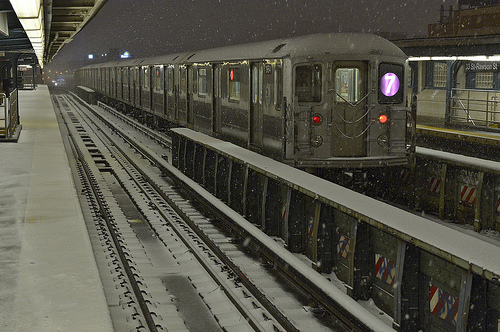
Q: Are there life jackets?
A: No, there are no life jackets.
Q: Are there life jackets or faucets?
A: No, there are no life jackets or faucets.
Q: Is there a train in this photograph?
A: Yes, there is a train.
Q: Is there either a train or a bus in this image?
A: Yes, there is a train.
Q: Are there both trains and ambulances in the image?
A: No, there is a train but no ambulances.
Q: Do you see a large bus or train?
A: Yes, there is a large train.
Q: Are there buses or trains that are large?
A: Yes, the train is large.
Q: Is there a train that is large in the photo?
A: Yes, there is a large train.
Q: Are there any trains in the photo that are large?
A: Yes, there is a train that is large.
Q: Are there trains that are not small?
A: Yes, there is a large train.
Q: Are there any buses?
A: No, there are no buses.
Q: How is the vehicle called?
A: The vehicle is a train.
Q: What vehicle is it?
A: The vehicle is a train.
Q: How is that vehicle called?
A: That is a train.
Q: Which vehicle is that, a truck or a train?
A: That is a train.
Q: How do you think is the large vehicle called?
A: The vehicle is a train.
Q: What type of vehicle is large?
A: The vehicle is a train.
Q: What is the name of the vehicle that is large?
A: The vehicle is a train.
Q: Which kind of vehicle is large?
A: The vehicle is a train.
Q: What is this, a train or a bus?
A: This is a train.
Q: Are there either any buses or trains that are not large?
A: No, there is a train but it is large.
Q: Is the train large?
A: Yes, the train is large.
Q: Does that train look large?
A: Yes, the train is large.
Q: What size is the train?
A: The train is large.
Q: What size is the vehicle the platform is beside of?
A: The train is large.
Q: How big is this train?
A: The train is large.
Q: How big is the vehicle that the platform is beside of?
A: The train is large.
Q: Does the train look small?
A: No, the train is large.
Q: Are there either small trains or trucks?
A: No, there is a train but it is large.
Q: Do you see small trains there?
A: No, there is a train but it is large.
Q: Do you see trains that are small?
A: No, there is a train but it is large.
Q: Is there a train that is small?
A: No, there is a train but it is large.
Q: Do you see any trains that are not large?
A: No, there is a train but it is large.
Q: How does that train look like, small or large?
A: The train is large.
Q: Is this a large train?
A: Yes, this is a large train.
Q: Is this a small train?
A: No, this is a large train.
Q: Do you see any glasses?
A: No, there are no glasses.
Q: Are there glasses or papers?
A: No, there are no glasses or papers.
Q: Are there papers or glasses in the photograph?
A: No, there are no glasses or papers.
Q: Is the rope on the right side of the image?
A: Yes, the rope is on the right of the image.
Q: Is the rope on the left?
A: No, the rope is on the right of the image.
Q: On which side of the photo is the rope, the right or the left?
A: The rope is on the right of the image.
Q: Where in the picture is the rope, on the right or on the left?
A: The rope is on the right of the image.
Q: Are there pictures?
A: No, there are no pictures.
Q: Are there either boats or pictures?
A: No, there are no pictures or boats.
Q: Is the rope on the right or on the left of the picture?
A: The rope is on the right of the image.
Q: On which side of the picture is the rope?
A: The rope is on the right of the image.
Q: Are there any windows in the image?
A: Yes, there is a window.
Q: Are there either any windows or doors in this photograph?
A: Yes, there is a window.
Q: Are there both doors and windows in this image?
A: Yes, there are both a window and a door.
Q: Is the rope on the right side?
A: Yes, the rope is on the right of the image.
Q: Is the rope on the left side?
A: No, the rope is on the right of the image.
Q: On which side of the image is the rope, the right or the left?
A: The rope is on the right of the image.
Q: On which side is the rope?
A: The rope is on the right of the image.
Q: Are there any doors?
A: Yes, there is a door.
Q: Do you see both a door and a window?
A: Yes, there are both a door and a window.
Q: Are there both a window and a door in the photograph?
A: Yes, there are both a door and a window.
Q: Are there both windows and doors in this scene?
A: Yes, there are both a door and windows.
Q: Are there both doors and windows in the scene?
A: Yes, there are both a door and windows.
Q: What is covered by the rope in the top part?
A: The door is covered by the rope.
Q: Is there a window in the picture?
A: Yes, there is a window.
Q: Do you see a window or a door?
A: Yes, there is a window.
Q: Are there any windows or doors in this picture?
A: Yes, there is a window.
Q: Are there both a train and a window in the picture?
A: Yes, there are both a window and a train.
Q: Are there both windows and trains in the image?
A: Yes, there are both a window and a train.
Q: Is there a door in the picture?
A: Yes, there is a door.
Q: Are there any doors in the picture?
A: Yes, there is a door.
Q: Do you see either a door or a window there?
A: Yes, there is a door.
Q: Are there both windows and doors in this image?
A: Yes, there are both a door and a window.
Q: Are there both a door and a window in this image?
A: Yes, there are both a door and a window.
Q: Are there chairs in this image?
A: No, there are no chairs.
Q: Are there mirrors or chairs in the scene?
A: No, there are no chairs or mirrors.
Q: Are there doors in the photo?
A: Yes, there is a door.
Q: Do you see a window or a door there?
A: Yes, there is a door.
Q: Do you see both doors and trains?
A: Yes, there are both a door and a train.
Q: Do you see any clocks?
A: No, there are no clocks.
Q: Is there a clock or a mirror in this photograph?
A: No, there are no clocks or mirrors.